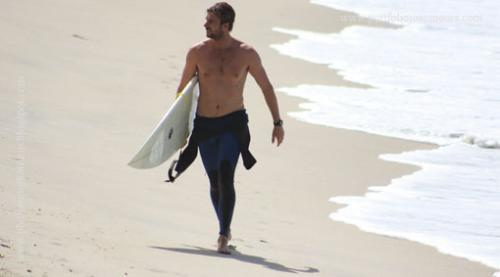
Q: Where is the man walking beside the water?
A: Beach.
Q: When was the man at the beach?
A: Summer time.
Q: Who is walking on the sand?
A: Surfer.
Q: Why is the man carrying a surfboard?
A: To surf.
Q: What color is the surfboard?
A: White.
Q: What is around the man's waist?
A: Long sleeve wet-shirt.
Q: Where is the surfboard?
A: Under the surfer's right arm.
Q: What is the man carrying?
A: Surfboard.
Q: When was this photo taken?
A: During the summer.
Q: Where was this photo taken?
A: Beach.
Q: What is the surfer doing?
A: Walking on the beach?.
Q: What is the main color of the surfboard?
A: White.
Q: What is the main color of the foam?
A: White.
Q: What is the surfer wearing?
A: Wetsuit.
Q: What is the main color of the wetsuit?
A: Blue and black.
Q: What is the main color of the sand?
A: Brown.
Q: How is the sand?
A: Smooth.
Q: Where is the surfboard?
A: Under man's arm.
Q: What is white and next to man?
A: The waves.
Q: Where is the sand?
A: Below the man.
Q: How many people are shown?
A: One.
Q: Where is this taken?
A: Beach.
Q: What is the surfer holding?
A: Surfboard.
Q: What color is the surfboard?
A: White.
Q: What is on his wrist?
A: Watch.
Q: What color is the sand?
A: Brown.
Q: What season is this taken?
A: Summer.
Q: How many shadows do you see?
A: One.